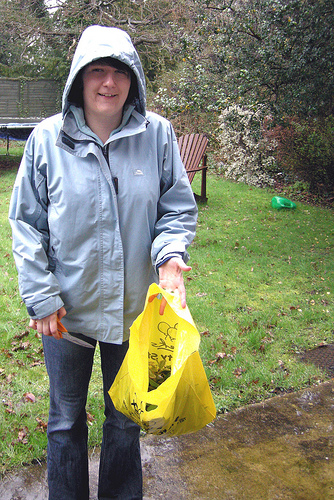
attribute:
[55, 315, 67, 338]
orange sissors — handled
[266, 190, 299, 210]
cover — metal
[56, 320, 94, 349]
scissors — orange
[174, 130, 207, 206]
chair — brown, adirondack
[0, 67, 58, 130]
fence — tall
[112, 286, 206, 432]
bag — yellow, plastic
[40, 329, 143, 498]
jeans — blue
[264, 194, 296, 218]
container — green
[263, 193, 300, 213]
container — green, plastic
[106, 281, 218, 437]
bag — yellow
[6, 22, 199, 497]
person — rained on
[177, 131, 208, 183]
slats — brown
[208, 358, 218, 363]
leaf — dead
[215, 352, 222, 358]
leaf — dead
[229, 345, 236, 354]
leaf — dead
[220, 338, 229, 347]
leaf — dead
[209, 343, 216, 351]
leaf — dead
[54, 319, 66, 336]
handle — orange